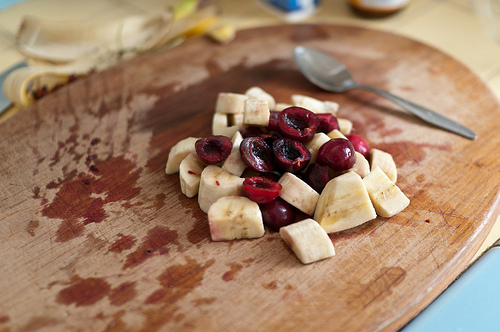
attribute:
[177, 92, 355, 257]
bananas & cherries — piled, chopped, together, sliced, cut up, cut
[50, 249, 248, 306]
cutting board — wooden, stained, on countertop, brown, wet, oval, moist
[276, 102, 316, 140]
cherry — halved, sliced, cut in half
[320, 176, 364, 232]
banana — chunked, chopped, sliced, cut up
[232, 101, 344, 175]
cherries — chunked, halved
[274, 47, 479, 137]
spoon — silver, shiny metal, metal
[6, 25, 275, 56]
banana peel — in background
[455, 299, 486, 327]
countertop — blue, wooden